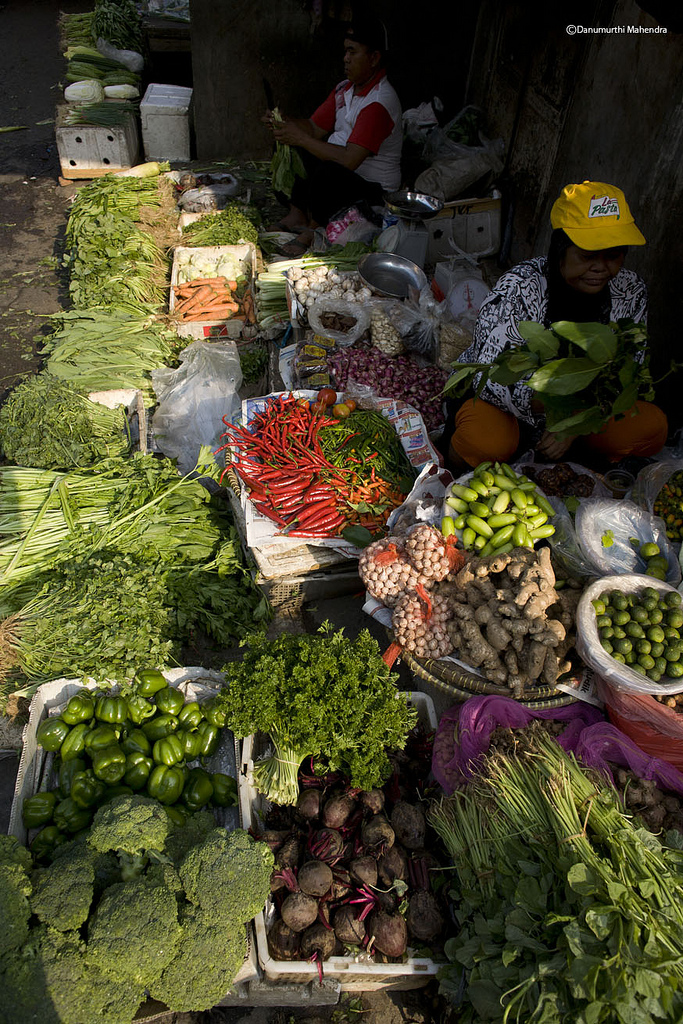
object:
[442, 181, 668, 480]
person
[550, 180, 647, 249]
yellow hat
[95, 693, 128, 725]
green pepper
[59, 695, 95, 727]
green pepper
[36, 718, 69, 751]
green pepper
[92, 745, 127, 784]
green pepper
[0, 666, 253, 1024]
tub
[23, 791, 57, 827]
green pepper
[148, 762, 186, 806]
green pepper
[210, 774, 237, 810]
green pepper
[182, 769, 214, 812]
green pepper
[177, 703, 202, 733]
green pepper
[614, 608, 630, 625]
green lime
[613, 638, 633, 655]
green lime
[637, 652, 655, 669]
green lime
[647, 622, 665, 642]
green lime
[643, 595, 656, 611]
green lime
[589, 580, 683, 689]
basket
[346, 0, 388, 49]
hat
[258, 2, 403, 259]
man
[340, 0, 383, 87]
head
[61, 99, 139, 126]
green onions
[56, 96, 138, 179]
box